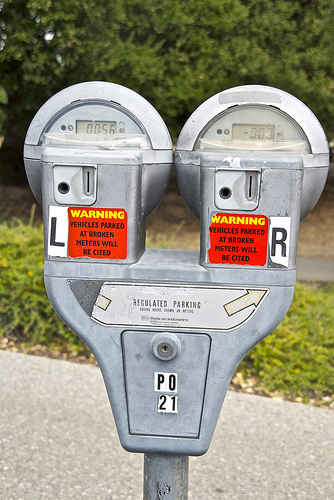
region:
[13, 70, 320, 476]
Parking meter with two sides and slots for coins.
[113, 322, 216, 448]
Locked section of parking meter that holds coins.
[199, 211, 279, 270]
Sticker giving a warning about parking at broken meters.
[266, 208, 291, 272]
Sticker indicating the right parking meter.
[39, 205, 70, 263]
Sticker indicating the left parking meter.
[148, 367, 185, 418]
Stickers that say "PO 21".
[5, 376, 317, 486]
Concrete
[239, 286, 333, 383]
Grass on ground behind meter.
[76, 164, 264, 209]
Slots for coins.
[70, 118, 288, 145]
Digital displays that indicate time left on meter.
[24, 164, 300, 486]
Parking meter.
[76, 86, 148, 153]
Parking meter with 56 minutes.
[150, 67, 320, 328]
Parking meter on the curb.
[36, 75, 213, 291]
Warning sticker on the meter.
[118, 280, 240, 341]
Regulated parking.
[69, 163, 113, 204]
Coin slot on the meter.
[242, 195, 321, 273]
Right meter.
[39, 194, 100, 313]
Left parking meter.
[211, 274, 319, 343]
Arrow on the parking meter.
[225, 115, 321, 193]
Zero time left on the parking meter.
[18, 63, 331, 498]
Parking meter on the stret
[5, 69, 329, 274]
Double parking meters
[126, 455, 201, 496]
Pole holding two parking meters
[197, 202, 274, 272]
Warning red label on right side of parking meter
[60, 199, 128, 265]
Warning red label on left side of parking meter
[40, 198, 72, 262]
Label with a letter L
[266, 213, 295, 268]
Label with a letter R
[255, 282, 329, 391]
Grass on back of parking meter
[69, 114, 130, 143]
Screen to display the time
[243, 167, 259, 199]
Slot for money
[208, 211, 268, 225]
Yellow word that says warning.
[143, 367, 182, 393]
Two black letters p and o.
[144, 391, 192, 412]
21 Written in black.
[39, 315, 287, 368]
Key hole for a parking meter.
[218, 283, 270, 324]
Arrow outlined in black.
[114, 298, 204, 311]
Sign that says regulated parking.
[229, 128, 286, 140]
Digits that read 000.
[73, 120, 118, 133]
Digits that read 0056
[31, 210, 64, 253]
Black letter L.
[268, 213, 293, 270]
Black letter R.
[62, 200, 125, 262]
red, black and yellow warning label on parking meter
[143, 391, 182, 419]
parking meter number 21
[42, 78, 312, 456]
silver parking meter for two parking spots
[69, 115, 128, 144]
56 minutes left on Left parking spot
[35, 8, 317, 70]
tall green leafy trees behind parking meter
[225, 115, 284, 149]
0 minutes left on right parking spot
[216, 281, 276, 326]
arrow pointing to right parking spot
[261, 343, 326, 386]
bright green bushes lining sidewalk behind parking meter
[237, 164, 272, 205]
slot to place quarters in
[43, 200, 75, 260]
Large black "L" to indicate left parking spot